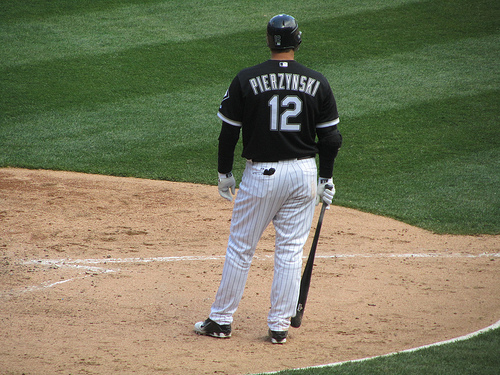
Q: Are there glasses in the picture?
A: No, there are no glasses.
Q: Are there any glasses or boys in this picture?
A: No, there are no glasses or boys.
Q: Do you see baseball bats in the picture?
A: Yes, there is a baseball bat.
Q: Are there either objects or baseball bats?
A: Yes, there is a baseball bat.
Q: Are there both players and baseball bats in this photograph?
A: Yes, there are both a baseball bat and a player.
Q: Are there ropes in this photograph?
A: No, there are no ropes.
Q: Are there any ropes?
A: No, there are no ropes.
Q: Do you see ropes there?
A: No, there are no ropes.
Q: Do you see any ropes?
A: No, there are no ropes.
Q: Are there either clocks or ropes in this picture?
A: No, there are no ropes or clocks.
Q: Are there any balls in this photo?
A: No, there are no balls.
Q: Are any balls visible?
A: No, there are no balls.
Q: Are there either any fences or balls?
A: No, there are no balls or fences.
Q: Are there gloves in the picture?
A: Yes, there are gloves.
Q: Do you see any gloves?
A: Yes, there are gloves.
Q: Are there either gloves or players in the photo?
A: Yes, there are gloves.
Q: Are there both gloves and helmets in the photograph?
A: Yes, there are both gloves and a helmet.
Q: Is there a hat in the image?
A: No, there are no hats.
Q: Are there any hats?
A: No, there are no hats.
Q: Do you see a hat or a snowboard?
A: No, there are no hats or snowboards.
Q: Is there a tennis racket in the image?
A: No, there are no rackets.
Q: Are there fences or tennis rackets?
A: No, there are no tennis rackets or fences.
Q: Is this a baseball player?
A: Yes, this is a baseball player.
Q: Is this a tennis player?
A: No, this is a baseball player.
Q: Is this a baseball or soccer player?
A: This is a baseball player.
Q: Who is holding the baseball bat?
A: The player is holding the baseball bat.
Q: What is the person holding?
A: The player is holding the baseball bat.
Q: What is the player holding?
A: The player is holding the baseball bat.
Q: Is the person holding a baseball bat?
A: Yes, the player is holding a baseball bat.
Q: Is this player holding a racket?
A: No, the player is holding a baseball bat.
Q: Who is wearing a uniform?
A: The player is wearing a uniform.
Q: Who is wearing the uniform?
A: The player is wearing a uniform.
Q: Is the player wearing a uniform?
A: Yes, the player is wearing a uniform.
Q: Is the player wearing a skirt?
A: No, the player is wearing a uniform.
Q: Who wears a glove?
A: The player wears a glove.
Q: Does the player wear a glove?
A: Yes, the player wears a glove.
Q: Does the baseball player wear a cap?
A: No, the player wears a glove.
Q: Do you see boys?
A: No, there are no boys.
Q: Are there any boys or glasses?
A: No, there are no boys or glasses.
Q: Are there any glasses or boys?
A: No, there are no boys or glasses.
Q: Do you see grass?
A: Yes, there is grass.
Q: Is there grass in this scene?
A: Yes, there is grass.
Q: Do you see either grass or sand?
A: Yes, there is grass.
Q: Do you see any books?
A: No, there are no books.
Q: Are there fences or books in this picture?
A: No, there are no books or fences.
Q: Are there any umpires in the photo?
A: No, there are no umpires.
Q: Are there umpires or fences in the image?
A: No, there are no umpires or fences.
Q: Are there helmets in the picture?
A: Yes, there is a helmet.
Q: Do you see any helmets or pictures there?
A: Yes, there is a helmet.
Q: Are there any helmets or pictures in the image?
A: Yes, there is a helmet.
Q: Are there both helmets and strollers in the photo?
A: No, there is a helmet but no strollers.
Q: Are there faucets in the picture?
A: No, there are no faucets.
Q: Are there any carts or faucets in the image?
A: No, there are no faucets or carts.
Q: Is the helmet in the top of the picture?
A: Yes, the helmet is in the top of the image.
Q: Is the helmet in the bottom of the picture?
A: No, the helmet is in the top of the image.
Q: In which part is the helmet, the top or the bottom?
A: The helmet is in the top of the image.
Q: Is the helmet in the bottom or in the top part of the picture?
A: The helmet is in the top of the image.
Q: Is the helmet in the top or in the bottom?
A: The helmet is in the top of the image.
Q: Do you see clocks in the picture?
A: No, there are no clocks.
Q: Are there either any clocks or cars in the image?
A: No, there are no clocks or cars.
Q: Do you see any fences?
A: No, there are no fences.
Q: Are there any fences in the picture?
A: No, there are no fences.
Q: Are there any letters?
A: Yes, there are letters.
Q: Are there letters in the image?
A: Yes, there are letters.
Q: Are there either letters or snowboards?
A: Yes, there are letters.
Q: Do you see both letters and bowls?
A: No, there are letters but no bowls.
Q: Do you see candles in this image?
A: No, there are no candles.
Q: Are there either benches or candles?
A: No, there are no candles or benches.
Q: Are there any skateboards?
A: No, there are no skateboards.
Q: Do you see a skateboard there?
A: No, there are no skateboards.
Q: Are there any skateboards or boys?
A: No, there are no skateboards or boys.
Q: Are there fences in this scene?
A: No, there are no fences.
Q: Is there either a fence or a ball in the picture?
A: No, there are no fences or balls.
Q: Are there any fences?
A: No, there are no fences.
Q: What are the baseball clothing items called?
A: The clothing items are pants.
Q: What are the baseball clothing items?
A: The clothing items are pants.